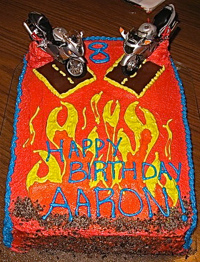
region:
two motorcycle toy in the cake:
[23, 5, 180, 71]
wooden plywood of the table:
[75, 6, 123, 25]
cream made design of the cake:
[32, 105, 185, 218]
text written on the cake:
[44, 126, 180, 225]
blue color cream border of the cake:
[170, 71, 197, 254]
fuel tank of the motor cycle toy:
[138, 21, 153, 34]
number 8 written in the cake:
[87, 37, 110, 64]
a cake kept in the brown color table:
[6, 4, 181, 235]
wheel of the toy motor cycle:
[66, 56, 89, 79]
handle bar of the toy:
[63, 29, 89, 46]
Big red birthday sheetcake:
[1, 35, 197, 260]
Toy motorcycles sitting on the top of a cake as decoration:
[22, 3, 178, 77]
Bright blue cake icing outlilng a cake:
[2, 35, 197, 249]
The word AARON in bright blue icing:
[36, 185, 170, 221]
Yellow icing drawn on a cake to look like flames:
[21, 90, 179, 207]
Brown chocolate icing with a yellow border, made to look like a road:
[30, 58, 96, 98]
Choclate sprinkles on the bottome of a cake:
[0, 194, 198, 260]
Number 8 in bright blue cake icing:
[87, 40, 111, 63]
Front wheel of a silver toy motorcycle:
[64, 54, 88, 78]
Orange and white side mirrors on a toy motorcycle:
[119, 26, 151, 45]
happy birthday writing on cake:
[41, 131, 186, 189]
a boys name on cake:
[45, 185, 177, 225]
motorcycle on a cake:
[22, 8, 88, 86]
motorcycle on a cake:
[114, 1, 178, 81]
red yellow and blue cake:
[16, 84, 186, 213]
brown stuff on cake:
[9, 188, 191, 252]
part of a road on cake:
[38, 46, 90, 102]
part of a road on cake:
[103, 50, 154, 96]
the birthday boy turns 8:
[85, 35, 113, 71]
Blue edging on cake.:
[187, 187, 199, 226]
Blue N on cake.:
[145, 187, 171, 214]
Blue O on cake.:
[118, 184, 137, 225]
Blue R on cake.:
[92, 188, 114, 231]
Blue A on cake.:
[74, 187, 90, 227]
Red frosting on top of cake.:
[19, 157, 140, 229]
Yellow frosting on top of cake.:
[143, 157, 179, 200]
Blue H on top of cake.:
[120, 161, 144, 189]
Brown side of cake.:
[57, 241, 114, 258]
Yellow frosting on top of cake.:
[25, 156, 55, 179]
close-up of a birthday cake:
[6, 4, 196, 252]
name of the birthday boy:
[40, 184, 186, 226]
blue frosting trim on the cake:
[0, 196, 10, 244]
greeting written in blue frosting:
[42, 134, 182, 184]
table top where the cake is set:
[180, 40, 196, 82]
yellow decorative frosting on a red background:
[24, 100, 76, 138]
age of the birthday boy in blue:
[86, 40, 110, 64]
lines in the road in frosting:
[30, 64, 72, 98]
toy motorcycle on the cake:
[22, 8, 88, 88]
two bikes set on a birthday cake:
[18, 6, 190, 96]